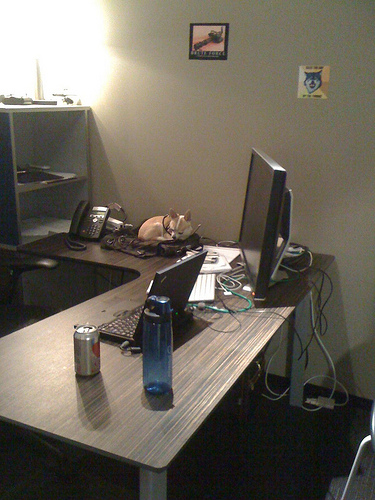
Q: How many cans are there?
A: 1.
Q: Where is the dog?
A: Beside the computer.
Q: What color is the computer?
A: Black.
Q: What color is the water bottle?
A: Blue.